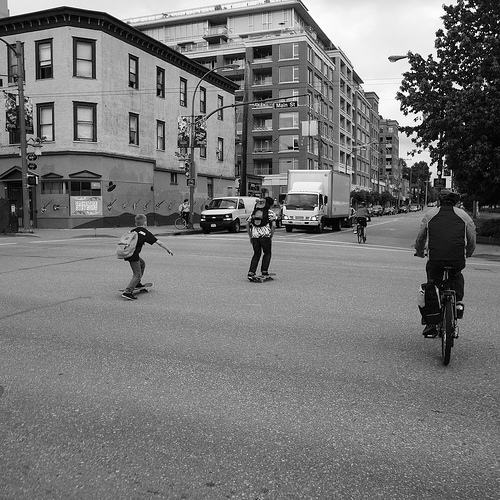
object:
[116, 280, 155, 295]
skateboard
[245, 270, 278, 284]
skateboard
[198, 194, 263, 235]
van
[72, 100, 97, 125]
window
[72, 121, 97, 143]
window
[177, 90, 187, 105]
window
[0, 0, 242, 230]
building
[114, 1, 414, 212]
building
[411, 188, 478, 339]
man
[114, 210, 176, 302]
boy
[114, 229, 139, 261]
backpack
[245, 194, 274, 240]
backpack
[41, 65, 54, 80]
window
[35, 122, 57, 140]
window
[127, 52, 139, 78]
window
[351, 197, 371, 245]
man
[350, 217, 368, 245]
bicycle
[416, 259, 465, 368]
bicycle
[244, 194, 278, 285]
guy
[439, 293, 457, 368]
wheel